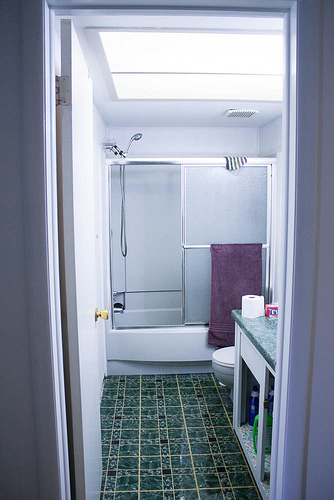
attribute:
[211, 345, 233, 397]
toilet — white 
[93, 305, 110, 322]
knob — door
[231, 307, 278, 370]
countertop — Green 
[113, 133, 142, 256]
shower attachment — silver shower 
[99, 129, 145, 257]
shower — Chrome finish telephone 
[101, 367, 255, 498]
floor — green tiles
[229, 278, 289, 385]
counter — green 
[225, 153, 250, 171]
wash cloth — striped wash 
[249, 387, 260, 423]
toilet cleaner — blue toilet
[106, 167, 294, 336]
door — shower , opened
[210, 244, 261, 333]
towel — purple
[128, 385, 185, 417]
flooring — Green laminated 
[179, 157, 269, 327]
shower door — shower 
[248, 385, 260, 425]
cleaning supply — supplies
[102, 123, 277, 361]
shower —  door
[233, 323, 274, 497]
cabinet — no door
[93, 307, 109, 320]
handle — gold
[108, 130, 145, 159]
faucet — metallic shower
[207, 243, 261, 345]
towel — wine color, large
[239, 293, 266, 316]
toilet paper — white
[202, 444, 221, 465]
floor — green marble tiled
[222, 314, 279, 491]
cabinet — without doors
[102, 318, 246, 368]
bathtub — Enclosed 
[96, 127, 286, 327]
door —  sliding glass 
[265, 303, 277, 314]
box — red, blue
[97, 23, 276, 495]
bathroom — ordered clean 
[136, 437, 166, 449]
tiles — green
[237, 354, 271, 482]
cabinet — bathroom 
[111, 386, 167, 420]
tile — green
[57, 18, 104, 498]
door — white